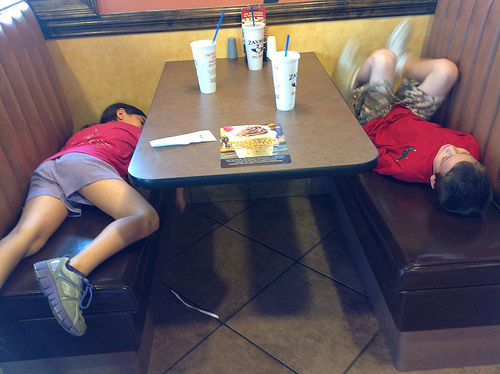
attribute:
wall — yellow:
[42, 9, 438, 204]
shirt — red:
[61, 100, 202, 178]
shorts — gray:
[35, 144, 159, 189]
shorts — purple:
[19, 146, 134, 208]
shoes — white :
[387, 20, 412, 75]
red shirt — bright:
[383, 115, 436, 172]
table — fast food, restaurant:
[123, 47, 377, 198]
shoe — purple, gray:
[29, 254, 101, 351]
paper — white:
[167, 285, 225, 325]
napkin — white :
[146, 127, 218, 149]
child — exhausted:
[24, 86, 156, 267]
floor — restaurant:
[222, 232, 319, 323]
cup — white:
[270, 47, 297, 112]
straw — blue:
[208, 9, 225, 43]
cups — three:
[183, 18, 310, 125]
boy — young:
[331, 9, 495, 230]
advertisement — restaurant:
[222, 122, 292, 169]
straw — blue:
[281, 29, 292, 53]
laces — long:
[77, 272, 92, 312]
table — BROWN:
[131, 52, 381, 181]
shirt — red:
[362, 105, 479, 182]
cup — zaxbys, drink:
[272, 50, 303, 115]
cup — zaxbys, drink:
[238, 15, 269, 74]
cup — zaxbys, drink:
[190, 38, 217, 94]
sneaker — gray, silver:
[34, 252, 98, 341]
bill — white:
[145, 124, 217, 153]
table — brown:
[127, 50, 377, 354]